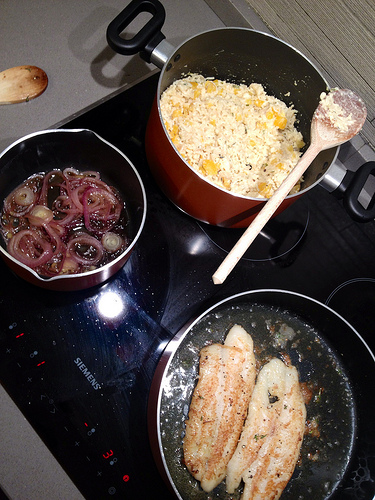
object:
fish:
[183, 324, 256, 492]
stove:
[1, 68, 366, 496]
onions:
[16, 188, 34, 206]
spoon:
[210, 85, 367, 283]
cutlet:
[183, 323, 257, 492]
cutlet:
[225, 357, 306, 498]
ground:
[286, 94, 312, 114]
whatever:
[157, 67, 312, 200]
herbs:
[233, 109, 282, 166]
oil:
[213, 313, 349, 468]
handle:
[317, 156, 374, 221]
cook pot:
[106, 0, 375, 231]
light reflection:
[91, 286, 131, 321]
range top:
[6, 42, 374, 489]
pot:
[1, 126, 148, 292]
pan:
[140, 282, 374, 496]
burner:
[198, 202, 311, 260]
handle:
[104, 1, 169, 54]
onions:
[59, 254, 69, 270]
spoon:
[0, 60, 47, 106]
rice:
[210, 86, 366, 291]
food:
[160, 68, 305, 195]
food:
[2, 161, 122, 279]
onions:
[65, 235, 105, 264]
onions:
[101, 231, 122, 250]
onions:
[80, 188, 122, 234]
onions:
[55, 187, 81, 215]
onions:
[7, 229, 53, 266]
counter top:
[0, 1, 187, 152]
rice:
[160, 74, 305, 206]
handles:
[129, 330, 171, 441]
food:
[175, 313, 324, 500]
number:
[103, 449, 114, 458]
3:
[97, 445, 122, 468]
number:
[37, 361, 46, 366]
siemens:
[71, 352, 109, 397]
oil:
[47, 186, 65, 205]